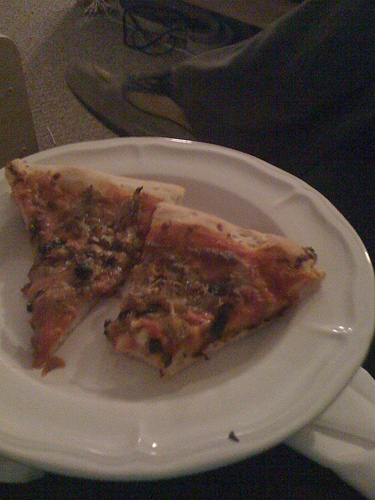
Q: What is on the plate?
A: Pizza.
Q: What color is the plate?
A: White.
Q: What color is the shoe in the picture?
A: Gray.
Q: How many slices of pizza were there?
A: 2.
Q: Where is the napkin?
A: Under the plate.